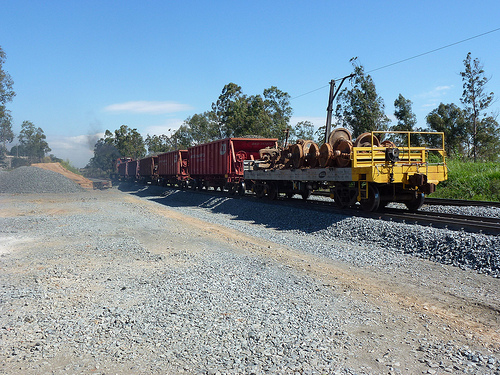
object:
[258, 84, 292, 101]
tops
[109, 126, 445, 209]
train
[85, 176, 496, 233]
track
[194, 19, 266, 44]
sky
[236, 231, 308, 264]
dirt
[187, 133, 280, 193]
cart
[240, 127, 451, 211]
truck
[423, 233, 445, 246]
stone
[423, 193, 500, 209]
rail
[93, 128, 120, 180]
tree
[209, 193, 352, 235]
shadow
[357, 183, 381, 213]
wheel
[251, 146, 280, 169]
object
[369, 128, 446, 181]
railing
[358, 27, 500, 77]
line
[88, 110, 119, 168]
smoke